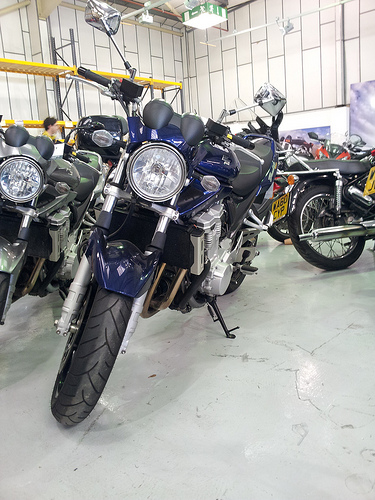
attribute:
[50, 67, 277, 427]
motorcycle — blue, black, green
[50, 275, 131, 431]
tire — black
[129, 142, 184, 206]
headlight — round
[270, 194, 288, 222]
license plate — black, yellow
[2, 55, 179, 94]
rack — yellow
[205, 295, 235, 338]
kickstand — up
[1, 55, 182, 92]
shelf — yellow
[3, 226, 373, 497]
floor — concrete